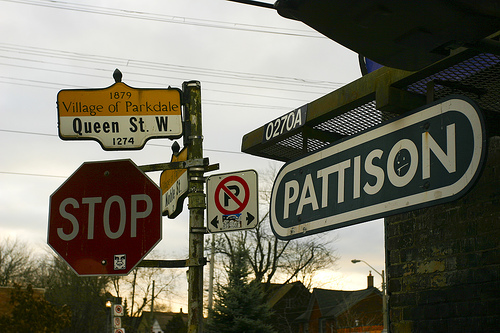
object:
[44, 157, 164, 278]
board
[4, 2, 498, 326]
view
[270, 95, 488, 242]
green sign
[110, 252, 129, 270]
sticker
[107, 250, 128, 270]
face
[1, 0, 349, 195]
wires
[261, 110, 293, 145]
numbers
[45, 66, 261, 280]
signs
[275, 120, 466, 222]
letters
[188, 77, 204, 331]
pole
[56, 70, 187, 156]
sign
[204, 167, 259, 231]
sign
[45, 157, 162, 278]
sign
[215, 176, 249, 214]
circle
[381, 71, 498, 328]
brick wall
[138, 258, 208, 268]
brace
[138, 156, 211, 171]
brace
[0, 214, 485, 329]
village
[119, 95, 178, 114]
parkdale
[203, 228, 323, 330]
tree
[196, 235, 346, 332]
trees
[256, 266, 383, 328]
houses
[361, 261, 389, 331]
pole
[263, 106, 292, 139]
number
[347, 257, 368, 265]
light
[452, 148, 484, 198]
corners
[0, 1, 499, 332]
air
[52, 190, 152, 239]
stop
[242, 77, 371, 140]
awning